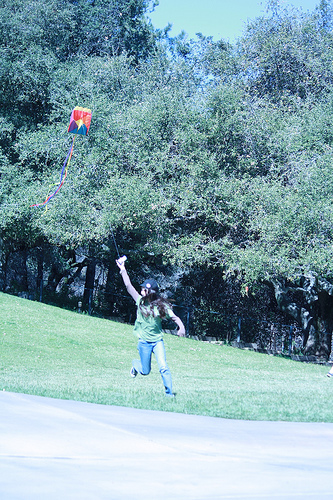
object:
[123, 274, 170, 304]
head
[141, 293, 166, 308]
hair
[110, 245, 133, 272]
hand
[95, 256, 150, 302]
arm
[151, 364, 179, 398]
foot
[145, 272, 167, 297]
hat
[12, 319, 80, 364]
grass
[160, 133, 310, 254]
trees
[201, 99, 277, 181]
leaves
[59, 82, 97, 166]
kite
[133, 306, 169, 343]
shirt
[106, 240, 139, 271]
handle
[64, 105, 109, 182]
piece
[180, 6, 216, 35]
air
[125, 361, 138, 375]
back foot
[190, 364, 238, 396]
ground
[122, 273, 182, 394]
girl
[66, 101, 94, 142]
red, blue, yellow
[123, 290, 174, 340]
wrinkles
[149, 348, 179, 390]
leg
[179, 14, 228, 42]
sky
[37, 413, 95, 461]
patch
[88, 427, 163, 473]
black asphalt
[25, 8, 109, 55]
dark